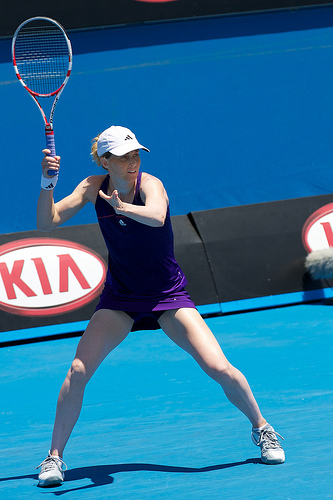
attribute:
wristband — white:
[37, 160, 66, 193]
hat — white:
[90, 115, 140, 156]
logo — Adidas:
[124, 135, 134, 142]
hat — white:
[92, 122, 152, 159]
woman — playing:
[36, 124, 284, 486]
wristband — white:
[39, 173, 60, 191]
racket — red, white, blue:
[10, 16, 73, 172]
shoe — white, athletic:
[252, 423, 285, 462]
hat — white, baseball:
[96, 127, 149, 155]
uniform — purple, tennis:
[93, 171, 198, 324]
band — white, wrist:
[38, 171, 60, 193]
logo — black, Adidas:
[44, 182, 55, 189]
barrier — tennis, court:
[2, 190, 328, 328]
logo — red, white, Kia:
[1, 237, 108, 320]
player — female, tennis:
[35, 127, 301, 490]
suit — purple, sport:
[84, 176, 197, 325]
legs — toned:
[61, 292, 288, 440]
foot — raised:
[223, 414, 299, 475]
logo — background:
[10, 222, 171, 302]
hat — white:
[79, 127, 187, 173]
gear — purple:
[79, 181, 212, 295]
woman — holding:
[15, 107, 237, 410]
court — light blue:
[35, 339, 329, 483]